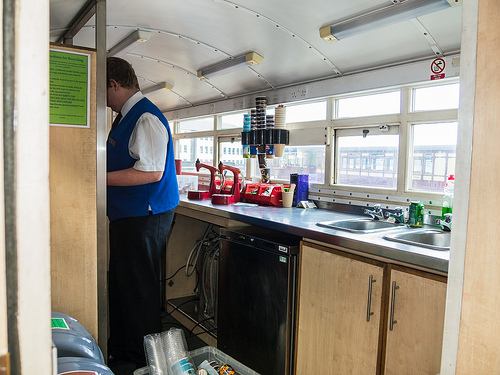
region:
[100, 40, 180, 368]
Man in blue vest.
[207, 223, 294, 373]
Small black refrigerator under counter.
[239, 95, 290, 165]
Cup dispenser holding many paper cups.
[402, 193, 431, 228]
Green aluminium can on counter.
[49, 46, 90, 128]
Green paper with white border.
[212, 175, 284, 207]
Row of red containers on counter.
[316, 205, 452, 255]
Two sinks on counter.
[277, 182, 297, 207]
Brown cup on counter.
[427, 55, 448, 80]
Red and white sign with black drawing.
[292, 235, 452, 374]
Two light brown cabinet doors.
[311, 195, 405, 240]
stainless steel sink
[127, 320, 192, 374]
package of clear plastic cups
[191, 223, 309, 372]
dishwasher with a black front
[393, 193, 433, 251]
aluminum green can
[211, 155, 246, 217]
red mixer sitting on counter trop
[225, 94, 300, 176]
rack of paper and plastic cups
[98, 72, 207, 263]
man wearing a blue vest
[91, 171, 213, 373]
man wearing black dress pants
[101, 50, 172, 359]
man standing in the small kitchen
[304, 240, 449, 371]
cabinets under the sinks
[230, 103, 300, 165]
cups in the window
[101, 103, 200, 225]
man is wearing a blue vest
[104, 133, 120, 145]
man has a name tag on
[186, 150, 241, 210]
two red drink mixers on the counter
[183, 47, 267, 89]
light on the ceiling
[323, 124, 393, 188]
window opens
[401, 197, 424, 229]
green can on the sink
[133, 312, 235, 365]
box on the floor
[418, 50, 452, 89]
A don't leave water on sign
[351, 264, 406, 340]
Black handles to a cabinet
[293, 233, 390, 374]
A brown cabinet under the sink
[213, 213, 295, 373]
A solid black dishwasher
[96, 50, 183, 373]
A man wearing a blue shirt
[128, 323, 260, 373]
Trash can full of trash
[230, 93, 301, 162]
A cup dispenser with many cups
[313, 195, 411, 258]
A sink with two faucets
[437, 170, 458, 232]
A half full bottle of dishwashing liquid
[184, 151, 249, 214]
Two red mixing machines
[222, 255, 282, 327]
the dishwasher is black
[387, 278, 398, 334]
handle on the cabinet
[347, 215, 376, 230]
the sink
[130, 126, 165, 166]
a white shirt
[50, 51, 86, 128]
a sign on the wall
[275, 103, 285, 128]
cups stacked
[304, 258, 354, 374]
a brown cabinet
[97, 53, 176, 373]
Medium sized white man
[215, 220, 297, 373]
solid black dishwasher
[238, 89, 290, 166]
Stack of beverage containers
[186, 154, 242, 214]
Bright red condiment dispensers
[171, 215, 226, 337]
Silver, grey, and black pipes and plumbing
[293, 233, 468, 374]
Two cabinets under the sink with wooden doors.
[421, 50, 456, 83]
Red, black, and white sign prohibiting something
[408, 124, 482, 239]
a window on the wall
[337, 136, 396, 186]
a window on the wall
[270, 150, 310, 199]
a window on the wall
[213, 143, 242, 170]
a window on the wall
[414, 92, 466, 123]
a window on the wall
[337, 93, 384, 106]
a window on the wall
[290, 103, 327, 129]
a window on the wall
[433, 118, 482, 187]
a window on the wall